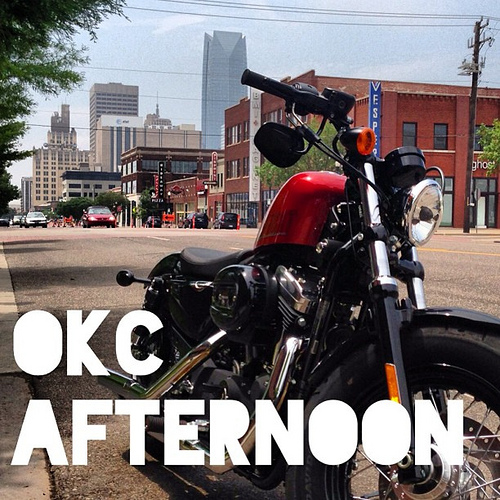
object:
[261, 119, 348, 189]
tree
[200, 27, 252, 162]
building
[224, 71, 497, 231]
building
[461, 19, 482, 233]
pole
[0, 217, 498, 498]
road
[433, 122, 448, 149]
window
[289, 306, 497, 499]
tire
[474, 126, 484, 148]
window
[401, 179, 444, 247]
headlight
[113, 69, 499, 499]
bike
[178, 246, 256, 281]
black seat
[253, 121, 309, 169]
side mirror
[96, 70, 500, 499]
motorbike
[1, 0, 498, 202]
sky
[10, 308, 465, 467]
letters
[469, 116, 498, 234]
tree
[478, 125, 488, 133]
leaf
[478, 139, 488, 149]
leaf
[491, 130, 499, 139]
leaf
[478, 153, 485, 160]
leaf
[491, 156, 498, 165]
leaf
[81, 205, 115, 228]
car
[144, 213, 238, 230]
parked cars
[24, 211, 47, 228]
car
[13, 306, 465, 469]
word phrase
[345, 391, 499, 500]
spokes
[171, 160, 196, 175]
window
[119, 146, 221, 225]
building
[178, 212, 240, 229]
street meter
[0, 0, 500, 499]
photo